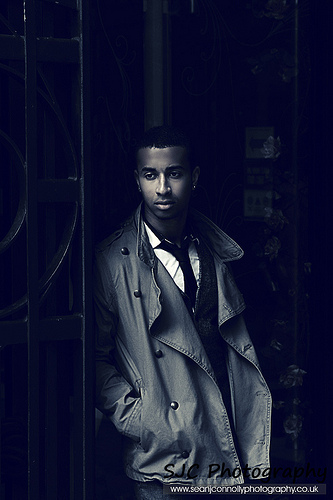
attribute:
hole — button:
[240, 339, 251, 353]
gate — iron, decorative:
[1, 0, 88, 499]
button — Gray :
[170, 402, 181, 411]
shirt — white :
[129, 215, 240, 318]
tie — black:
[159, 238, 199, 301]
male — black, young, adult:
[80, 128, 277, 490]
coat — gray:
[82, 196, 276, 486]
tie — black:
[152, 234, 202, 309]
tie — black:
[156, 237, 197, 305]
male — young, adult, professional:
[95, 125, 272, 499]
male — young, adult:
[88, 116, 303, 497]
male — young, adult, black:
[85, 106, 267, 472]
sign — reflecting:
[232, 115, 295, 223]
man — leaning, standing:
[91, 120, 297, 498]